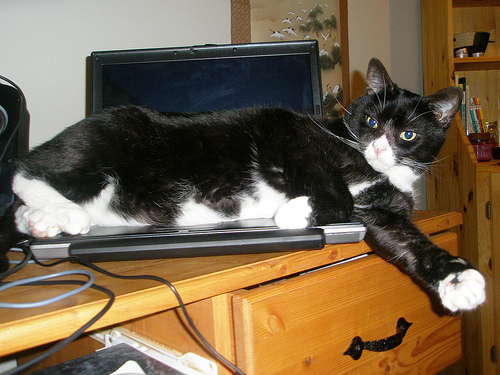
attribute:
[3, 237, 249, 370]
cord — black, electrical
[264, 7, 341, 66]
birds — white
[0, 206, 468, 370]
desk — wooden, brown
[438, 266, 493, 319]
paw — white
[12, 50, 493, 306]
cat — black, white, tuxedo, laying,  laying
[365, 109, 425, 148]
eyes — blue, yellow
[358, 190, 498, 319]
arm — black, white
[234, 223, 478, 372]
drawer — brown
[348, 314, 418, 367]
handle — black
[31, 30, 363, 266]
laptop — black, silver,  open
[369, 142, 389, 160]
nose tip — pink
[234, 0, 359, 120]
picture — framed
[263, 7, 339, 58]
birds — white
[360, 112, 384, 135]
cat eye — green, blue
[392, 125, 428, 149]
cat eye — blue, green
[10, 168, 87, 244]
cat paws — white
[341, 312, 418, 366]
handle — black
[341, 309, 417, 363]
handle — black, metal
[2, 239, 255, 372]
cords — various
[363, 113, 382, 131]
eye — dark blue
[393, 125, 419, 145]
eye — dark blue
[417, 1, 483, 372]
cabinet — wooden, light stained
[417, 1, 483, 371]
shelf — wooden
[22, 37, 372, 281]
laptop — black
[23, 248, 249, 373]
cord — black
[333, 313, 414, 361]
handle — black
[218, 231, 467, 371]
drawer — wooden, brown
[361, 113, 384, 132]
eye — blue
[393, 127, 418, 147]
eye — blue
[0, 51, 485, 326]
cat — black, white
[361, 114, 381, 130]
pupil — black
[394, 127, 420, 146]
pupil — black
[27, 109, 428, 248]
fur — white, black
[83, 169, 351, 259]
stomach — white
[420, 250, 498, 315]
paw — white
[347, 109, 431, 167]
eyes — yellow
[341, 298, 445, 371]
handle — black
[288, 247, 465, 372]
drawer — wood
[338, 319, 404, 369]
handle — metal